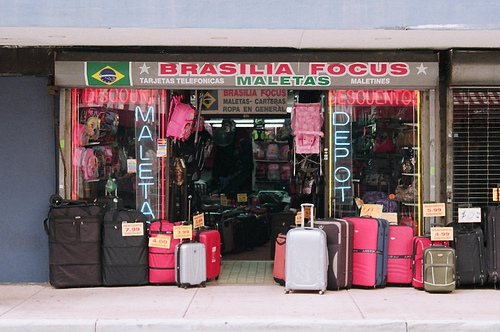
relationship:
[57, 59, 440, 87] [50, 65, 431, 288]
sign on storefront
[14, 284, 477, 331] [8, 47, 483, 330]
sidewalk in front of store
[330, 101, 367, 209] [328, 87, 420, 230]
sign in window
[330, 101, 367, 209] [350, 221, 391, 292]
sign above bag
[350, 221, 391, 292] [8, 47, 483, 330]
bag in front of store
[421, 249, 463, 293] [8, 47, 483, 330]
luggage in front of store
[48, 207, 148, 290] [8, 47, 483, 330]
bags in front of store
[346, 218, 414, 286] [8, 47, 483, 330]
bags in front of store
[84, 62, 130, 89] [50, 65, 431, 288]
flag on storefront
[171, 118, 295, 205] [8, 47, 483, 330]
inside of store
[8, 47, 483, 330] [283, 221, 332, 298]
store selling luggage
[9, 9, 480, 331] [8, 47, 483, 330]
picture of store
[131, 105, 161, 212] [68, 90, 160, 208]
maleta on window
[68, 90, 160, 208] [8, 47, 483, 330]
window of store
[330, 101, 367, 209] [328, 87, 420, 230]
depot on window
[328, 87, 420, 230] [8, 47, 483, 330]
window of store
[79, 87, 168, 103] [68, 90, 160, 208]
discount on window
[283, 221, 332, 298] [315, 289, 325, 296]
luggage with wheels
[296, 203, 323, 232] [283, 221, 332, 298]
handle of luggage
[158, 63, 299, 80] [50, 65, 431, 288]
brasilia on storefront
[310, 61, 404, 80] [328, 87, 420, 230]
focus on window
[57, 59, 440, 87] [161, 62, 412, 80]
sign with writing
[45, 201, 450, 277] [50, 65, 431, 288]
suitcases in storefront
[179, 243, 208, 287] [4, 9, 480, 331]
suitcase in picture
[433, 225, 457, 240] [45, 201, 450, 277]
tag on suitcases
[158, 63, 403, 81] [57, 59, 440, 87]
lettering on sign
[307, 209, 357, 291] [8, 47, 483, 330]
suitcase outside store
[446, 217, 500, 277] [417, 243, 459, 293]
suitcase next to luggage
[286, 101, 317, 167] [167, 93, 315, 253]
stroller in doorway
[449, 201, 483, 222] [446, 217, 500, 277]
sign on suitcase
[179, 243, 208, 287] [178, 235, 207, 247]
suitcase with handle